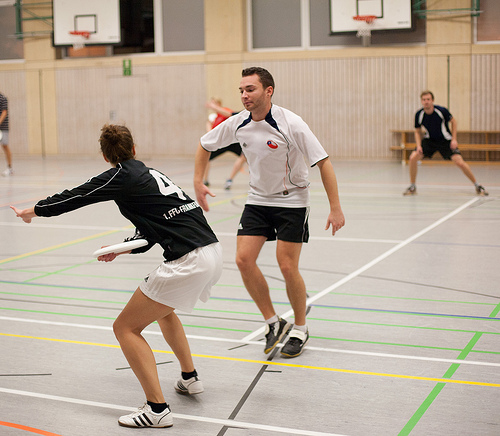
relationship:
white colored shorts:
[186, 282, 199, 292] [137, 241, 224, 312]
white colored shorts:
[186, 282, 199, 292] [1, 132, 11, 147]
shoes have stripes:
[117, 377, 204, 428] [133, 413, 152, 428]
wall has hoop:
[3, 3, 499, 159] [69, 30, 91, 50]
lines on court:
[312, 234, 493, 383] [3, 152, 494, 435]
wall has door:
[3, 3, 499, 159] [105, 75, 158, 158]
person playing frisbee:
[10, 125, 220, 427] [94, 239, 148, 258]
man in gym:
[193, 67, 344, 358] [3, 1, 497, 427]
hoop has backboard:
[69, 30, 91, 50] [55, 1, 122, 45]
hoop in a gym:
[69, 30, 91, 50] [3, 1, 497, 427]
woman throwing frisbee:
[10, 125, 220, 427] [94, 239, 148, 258]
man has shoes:
[403, 92, 488, 197] [402, 184, 490, 196]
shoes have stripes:
[265, 319, 309, 359] [291, 330, 307, 342]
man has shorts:
[403, 92, 488, 197] [417, 139, 461, 159]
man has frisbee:
[10, 125, 220, 427] [94, 239, 148, 258]